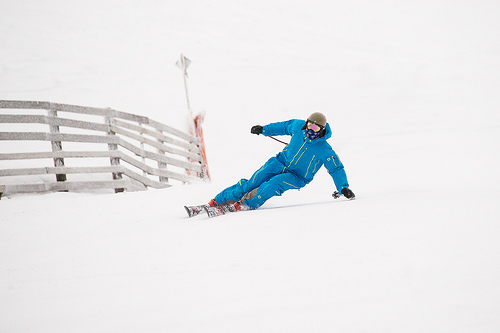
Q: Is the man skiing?
A: Yes, the man is skiing.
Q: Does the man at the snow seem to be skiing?
A: Yes, the man is skiing.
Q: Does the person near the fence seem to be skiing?
A: Yes, the man is skiing.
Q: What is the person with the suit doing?
A: The man is skiing.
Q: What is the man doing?
A: The man is skiing.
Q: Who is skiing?
A: The man is skiing.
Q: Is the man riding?
A: No, the man is skiing.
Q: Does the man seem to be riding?
A: No, the man is skiing.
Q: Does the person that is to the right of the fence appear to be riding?
A: No, the man is skiing.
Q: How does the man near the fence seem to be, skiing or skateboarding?
A: The man is skiing.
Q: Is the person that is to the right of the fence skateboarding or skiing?
A: The man is skiing.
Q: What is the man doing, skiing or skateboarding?
A: The man is skiing.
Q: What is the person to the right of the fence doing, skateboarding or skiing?
A: The man is skiing.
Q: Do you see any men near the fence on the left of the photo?
A: Yes, there is a man near the fence.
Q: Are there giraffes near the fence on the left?
A: No, there is a man near the fence.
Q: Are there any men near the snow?
A: Yes, there is a man near the snow.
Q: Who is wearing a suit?
A: The man is wearing a suit.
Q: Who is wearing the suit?
A: The man is wearing a suit.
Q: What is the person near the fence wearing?
A: The man is wearing a suit.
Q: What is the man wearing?
A: The man is wearing a suit.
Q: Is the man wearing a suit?
A: Yes, the man is wearing a suit.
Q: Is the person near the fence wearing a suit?
A: Yes, the man is wearing a suit.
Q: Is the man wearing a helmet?
A: No, the man is wearing a suit.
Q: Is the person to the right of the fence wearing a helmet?
A: No, the man is wearing a suit.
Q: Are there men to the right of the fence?
A: Yes, there is a man to the right of the fence.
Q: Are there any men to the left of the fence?
A: No, the man is to the right of the fence.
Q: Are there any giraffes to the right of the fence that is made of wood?
A: No, there is a man to the right of the fence.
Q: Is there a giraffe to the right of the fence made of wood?
A: No, there is a man to the right of the fence.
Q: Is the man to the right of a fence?
A: Yes, the man is to the right of a fence.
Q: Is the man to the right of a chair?
A: No, the man is to the right of a fence.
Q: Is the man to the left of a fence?
A: No, the man is to the right of a fence.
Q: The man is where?
A: The man is at the snow.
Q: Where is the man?
A: The man is at the snow.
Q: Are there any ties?
A: No, there are no ties.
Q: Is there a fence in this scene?
A: Yes, there is a fence.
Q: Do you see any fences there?
A: Yes, there is a fence.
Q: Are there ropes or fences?
A: Yes, there is a fence.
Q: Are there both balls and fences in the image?
A: No, there is a fence but no balls.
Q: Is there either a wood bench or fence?
A: Yes, there is a wood fence.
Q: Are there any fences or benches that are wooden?
A: Yes, the fence is wooden.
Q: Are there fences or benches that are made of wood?
A: Yes, the fence is made of wood.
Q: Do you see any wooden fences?
A: Yes, there is a wood fence.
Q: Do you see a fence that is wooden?
A: Yes, there is a fence that is wooden.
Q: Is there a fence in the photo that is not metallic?
A: Yes, there is a wooden fence.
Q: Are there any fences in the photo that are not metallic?
A: Yes, there is a wooden fence.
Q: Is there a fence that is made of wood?
A: Yes, there is a fence that is made of wood.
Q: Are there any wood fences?
A: Yes, there is a fence that is made of wood.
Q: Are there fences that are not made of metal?
A: Yes, there is a fence that is made of wood.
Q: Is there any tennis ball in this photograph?
A: No, there are no tennis balls.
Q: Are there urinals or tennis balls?
A: No, there are no tennis balls or urinals.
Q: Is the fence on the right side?
A: No, the fence is on the left of the image.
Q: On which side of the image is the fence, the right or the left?
A: The fence is on the left of the image.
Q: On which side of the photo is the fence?
A: The fence is on the left of the image.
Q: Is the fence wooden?
A: Yes, the fence is wooden.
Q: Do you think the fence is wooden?
A: Yes, the fence is wooden.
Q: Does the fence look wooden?
A: Yes, the fence is wooden.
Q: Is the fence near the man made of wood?
A: Yes, the fence is made of wood.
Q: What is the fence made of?
A: The fence is made of wood.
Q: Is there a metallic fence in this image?
A: No, there is a fence but it is wooden.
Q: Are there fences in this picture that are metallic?
A: No, there is a fence but it is wooden.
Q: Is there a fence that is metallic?
A: No, there is a fence but it is wooden.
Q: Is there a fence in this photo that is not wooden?
A: No, there is a fence but it is wooden.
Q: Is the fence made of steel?
A: No, the fence is made of wood.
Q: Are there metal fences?
A: No, there is a fence but it is made of wood.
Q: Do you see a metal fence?
A: No, there is a fence but it is made of wood.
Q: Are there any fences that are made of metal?
A: No, there is a fence but it is made of wood.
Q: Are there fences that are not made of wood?
A: No, there is a fence but it is made of wood.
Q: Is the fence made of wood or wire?
A: The fence is made of wood.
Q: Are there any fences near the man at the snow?
A: Yes, there is a fence near the man.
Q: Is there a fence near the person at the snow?
A: Yes, there is a fence near the man.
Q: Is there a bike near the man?
A: No, there is a fence near the man.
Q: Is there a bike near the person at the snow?
A: No, there is a fence near the man.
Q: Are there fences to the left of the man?
A: Yes, there is a fence to the left of the man.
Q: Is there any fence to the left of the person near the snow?
A: Yes, there is a fence to the left of the man.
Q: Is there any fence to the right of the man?
A: No, the fence is to the left of the man.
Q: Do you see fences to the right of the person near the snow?
A: No, the fence is to the left of the man.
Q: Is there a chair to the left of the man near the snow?
A: No, there is a fence to the left of the man.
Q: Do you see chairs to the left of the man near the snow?
A: No, there is a fence to the left of the man.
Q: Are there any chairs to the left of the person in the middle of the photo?
A: No, there is a fence to the left of the man.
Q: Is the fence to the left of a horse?
A: No, the fence is to the left of a man.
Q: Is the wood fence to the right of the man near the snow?
A: No, the fence is to the left of the man.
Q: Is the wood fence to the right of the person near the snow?
A: No, the fence is to the left of the man.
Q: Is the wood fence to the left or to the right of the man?
A: The fence is to the left of the man.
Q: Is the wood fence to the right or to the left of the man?
A: The fence is to the left of the man.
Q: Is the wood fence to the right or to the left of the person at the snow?
A: The fence is to the left of the man.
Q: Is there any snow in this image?
A: Yes, there is snow.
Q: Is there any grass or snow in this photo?
A: Yes, there is snow.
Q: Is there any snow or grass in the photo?
A: Yes, there is snow.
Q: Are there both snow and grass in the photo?
A: No, there is snow but no grass.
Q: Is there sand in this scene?
A: No, there is no sand.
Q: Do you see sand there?
A: No, there is no sand.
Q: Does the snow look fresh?
A: Yes, the snow is fresh.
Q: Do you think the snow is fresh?
A: Yes, the snow is fresh.